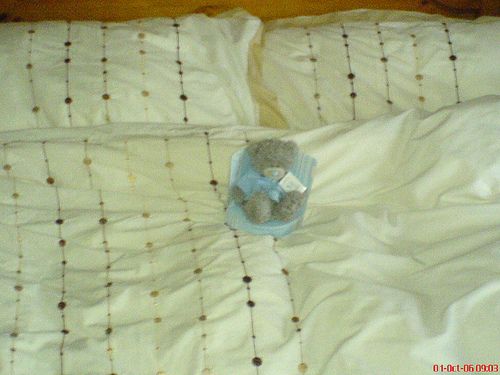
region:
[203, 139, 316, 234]
a blue object on the bed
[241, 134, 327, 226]
teddy bear on the bed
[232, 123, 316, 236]
the teddy bear is gray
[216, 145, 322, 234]
wearing a blue shirt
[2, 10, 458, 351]
the bed is white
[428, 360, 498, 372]
the text is red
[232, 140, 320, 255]
sitting on blue fabric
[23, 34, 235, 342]
brown lines on the bed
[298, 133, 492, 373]
this side has no lines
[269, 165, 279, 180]
his nose is blue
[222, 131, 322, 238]
snall stuffed bear on bed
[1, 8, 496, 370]
full size bed with two full pillows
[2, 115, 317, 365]
white bed linen with brown woven design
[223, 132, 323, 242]
small bear with blue bow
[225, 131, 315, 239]
small bear wearing blue sweater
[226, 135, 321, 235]
small brown bear on blue blanket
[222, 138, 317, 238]
tiny blue blanket under bear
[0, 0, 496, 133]
two white and brown bed pillows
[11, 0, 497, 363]
indoor bedroom scene with toy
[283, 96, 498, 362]
plain white side of decorated duvet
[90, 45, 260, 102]
Pillows on the bed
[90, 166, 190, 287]
A bed in the picture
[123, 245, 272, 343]
Bed cover on the bed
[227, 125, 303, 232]
Blue and gray bear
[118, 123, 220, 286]
A pattern on the bed covers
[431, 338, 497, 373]
Date on the photo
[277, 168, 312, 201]
A tag on the teddy bear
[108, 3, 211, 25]
Wood on the bed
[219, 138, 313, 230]
Teddy bear on the bed.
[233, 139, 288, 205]
blue shirt on the bear.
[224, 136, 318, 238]
blue blanket under the bear.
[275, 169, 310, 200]
Tag on the bear.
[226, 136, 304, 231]
brown color on the bear fur.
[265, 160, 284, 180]
blue nose on the bear.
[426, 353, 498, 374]
Red letters and numbers.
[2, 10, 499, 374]
Bed in the background.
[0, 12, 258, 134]
Pillow on the bed.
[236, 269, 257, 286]
dot on the blanket.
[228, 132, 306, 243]
a childs small teddy bear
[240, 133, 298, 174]
the head of a teddy bear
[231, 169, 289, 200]
the shirt of a teddy bear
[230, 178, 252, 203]
the arm of a teddy bear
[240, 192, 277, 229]
the right foot of a teddy bear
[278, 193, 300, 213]
the left foot of a teddy bear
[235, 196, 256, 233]
the blanket of a teddy bear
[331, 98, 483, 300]
a big white comforter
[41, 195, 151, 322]
a design on a comforter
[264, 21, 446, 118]
a big fluffy white pillow